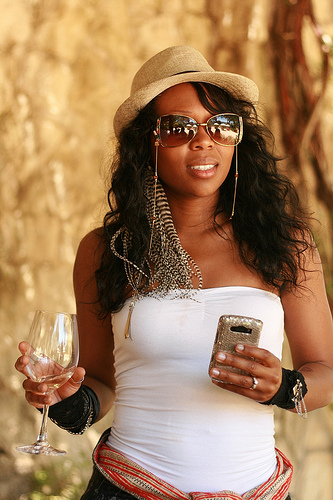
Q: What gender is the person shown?
A: Female.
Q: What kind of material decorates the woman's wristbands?
A: Metal.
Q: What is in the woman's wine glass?
A: White wine.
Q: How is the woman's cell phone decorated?
A: With a sequined phone case.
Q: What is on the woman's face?
A: Sunglasses.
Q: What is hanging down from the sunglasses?
A: Chains.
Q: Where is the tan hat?
A: On the woman's head.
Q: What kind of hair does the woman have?
A: Wavy.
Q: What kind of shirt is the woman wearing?
A: A white tube top.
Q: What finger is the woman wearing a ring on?
A: Right ring finger.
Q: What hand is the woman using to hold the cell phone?
A: Her left hand.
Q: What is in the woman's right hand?
A: Wine glass.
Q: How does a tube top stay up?
A: Elastic.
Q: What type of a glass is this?
A: Wine glass.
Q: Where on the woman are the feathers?
A: In her hair.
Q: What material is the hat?
A: Straw.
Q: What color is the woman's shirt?
A: White.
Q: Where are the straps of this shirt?
A: There are none.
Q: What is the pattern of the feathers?
A: Stripes.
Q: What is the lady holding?
A: A mobile.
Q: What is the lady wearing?
A: Clothes.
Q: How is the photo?
A: Clear.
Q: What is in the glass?
A: Wine.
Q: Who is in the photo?
A: A lady.